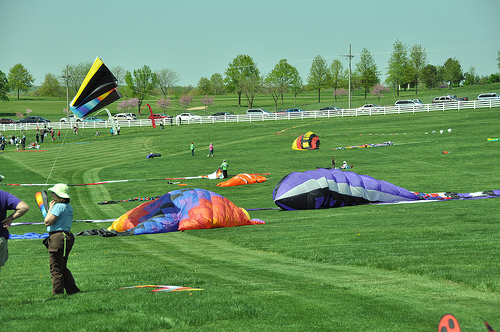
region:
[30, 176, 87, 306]
Person wearing brown slacks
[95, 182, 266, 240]
a rainbow colored balloon on the ground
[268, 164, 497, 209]
A blue balloon with a gray stripe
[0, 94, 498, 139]
A long white fence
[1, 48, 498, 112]
Trees behind the white fence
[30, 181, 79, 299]
A person wearing a white hat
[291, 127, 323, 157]
a black, yellow and red balloon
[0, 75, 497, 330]
a large grassy field with several kites on the ground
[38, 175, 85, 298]
a woman standing in a field flying a kite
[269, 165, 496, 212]
a purple, white and black kite on the grass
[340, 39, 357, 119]
a large telephone pole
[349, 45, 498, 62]
telephone wires, barely visable in the sky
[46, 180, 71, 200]
a woman's large shady hat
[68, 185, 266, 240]
a large colorful kite laying in the grass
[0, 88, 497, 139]
a long white picket fence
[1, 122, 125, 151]
a small crowd of people standing in the grass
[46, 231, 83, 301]
a woman's brown cargo pants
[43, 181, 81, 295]
woman wearing dark brown pants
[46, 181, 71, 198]
woman's white floppy cotton hat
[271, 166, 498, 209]
blue, silver and black deflated hot air balloon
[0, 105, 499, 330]
large bright green field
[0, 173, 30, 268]
man in a blue shirt standing with his hand on his hip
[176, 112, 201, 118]
white car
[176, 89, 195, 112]
small cherry blossom tree in bloom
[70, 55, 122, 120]
black, yellow and rainbow striped kite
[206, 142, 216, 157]
woman in a pink shirt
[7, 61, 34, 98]
tall green tree in the distance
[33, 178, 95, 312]
Woman white hat brown pants.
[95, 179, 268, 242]
Large multi-colored kite.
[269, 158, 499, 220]
Blue's and purple kite long tail.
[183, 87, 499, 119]
Row of cars along white fence.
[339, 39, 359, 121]
Telephone pole along road.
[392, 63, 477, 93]
House behind trees distance.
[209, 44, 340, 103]
Line of green trees.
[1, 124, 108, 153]
Group of people walking.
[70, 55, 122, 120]
a kite in flight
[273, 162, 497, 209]
a large kite on ground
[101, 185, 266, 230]
a large kite on ground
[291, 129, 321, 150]
a large kite on ground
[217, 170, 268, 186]
a large kite on ground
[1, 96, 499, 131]
a long white picket fence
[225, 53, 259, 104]
a large tree in distance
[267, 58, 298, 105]
a large tree in distance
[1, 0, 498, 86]
a hazy blue sky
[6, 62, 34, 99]
a large tree in distance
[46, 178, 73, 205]
tan sun hat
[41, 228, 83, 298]
brown cargo pants on woman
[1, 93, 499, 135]
long white fence